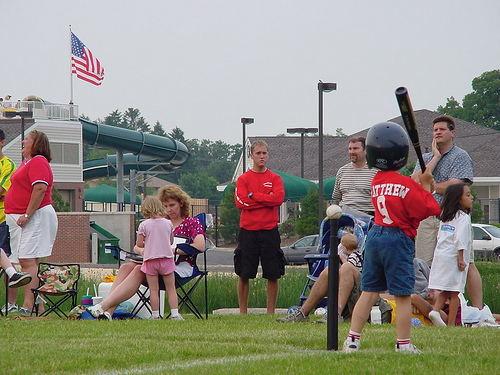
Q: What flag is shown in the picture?
A: American flag.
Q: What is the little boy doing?
A: Batting a ball.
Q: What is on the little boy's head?
A: A helmet.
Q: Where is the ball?
A: The ball is on the hitter's stand.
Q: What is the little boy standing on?
A: Grass.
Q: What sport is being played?
A: T-ball.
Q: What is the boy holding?
A: A bat.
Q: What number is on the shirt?
A: Nine.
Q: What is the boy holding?
A: A bat.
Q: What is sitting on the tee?
A: Baseball.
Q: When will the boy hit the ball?
A: When he swings.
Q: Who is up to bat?
A: The boy.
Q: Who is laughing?
A: The woman in the red shirt.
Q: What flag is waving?
A: American.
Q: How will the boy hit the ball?
A: With his bat.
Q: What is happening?
A: A tee ball game.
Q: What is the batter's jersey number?
A: Nine.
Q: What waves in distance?
A: An American flag.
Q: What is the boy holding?
A: A bat.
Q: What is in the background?
A: A slide.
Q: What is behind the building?
A: Tall trees.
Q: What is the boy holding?
A: A bat.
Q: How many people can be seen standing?
A: Seven.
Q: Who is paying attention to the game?
A: The fathers.